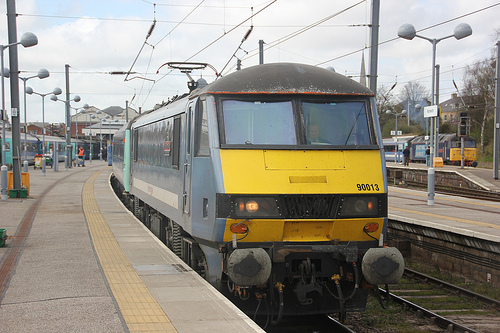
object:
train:
[1, 135, 112, 162]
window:
[303, 99, 370, 146]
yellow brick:
[78, 167, 178, 331]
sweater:
[75, 144, 86, 159]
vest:
[75, 145, 86, 159]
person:
[402, 143, 411, 168]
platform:
[386, 161, 499, 190]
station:
[0, 124, 499, 331]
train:
[383, 135, 477, 172]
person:
[75, 145, 85, 167]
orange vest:
[75, 147, 85, 157]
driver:
[304, 122, 332, 149]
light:
[236, 201, 247, 213]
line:
[75, 168, 174, 331]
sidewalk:
[0, 139, 265, 331]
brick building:
[437, 94, 492, 128]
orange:
[76, 146, 86, 155]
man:
[74, 144, 87, 167]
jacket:
[76, 148, 86, 154]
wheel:
[164, 222, 183, 257]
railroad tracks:
[409, 252, 477, 327]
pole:
[5, 0, 21, 187]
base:
[8, 186, 28, 198]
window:
[217, 98, 298, 145]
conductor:
[306, 98, 361, 148]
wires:
[150, 4, 478, 61]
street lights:
[412, 18, 464, 166]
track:
[389, 179, 496, 201]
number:
[355, 180, 381, 194]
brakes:
[222, 240, 406, 291]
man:
[378, 107, 441, 189]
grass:
[391, 273, 461, 304]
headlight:
[356, 196, 380, 216]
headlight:
[227, 194, 278, 217]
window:
[176, 100, 216, 189]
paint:
[217, 149, 386, 244]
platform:
[13, 151, 485, 314]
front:
[219, 150, 389, 257]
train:
[105, 58, 401, 324]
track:
[206, 215, 500, 332]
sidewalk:
[385, 157, 495, 185]